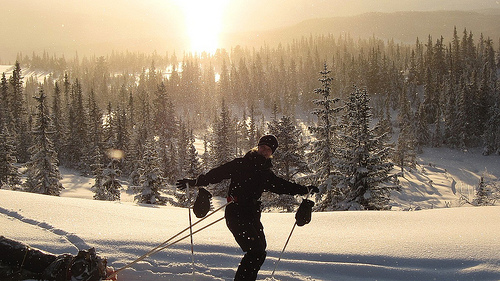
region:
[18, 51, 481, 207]
pine trees in the snow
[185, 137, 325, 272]
a person pulling a sled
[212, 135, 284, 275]
a person wearing a black shirt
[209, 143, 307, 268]
a person with a black cap on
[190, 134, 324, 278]
a person wearing black gloves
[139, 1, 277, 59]
the sun in the sky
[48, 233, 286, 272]
tracks in the snow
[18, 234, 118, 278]
the sled the person is holding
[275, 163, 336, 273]
the stick the person is holding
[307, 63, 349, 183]
a tall snowy tree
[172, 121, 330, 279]
person standing on the snow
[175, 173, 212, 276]
ski pole sticking in the snow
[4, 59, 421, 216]
trees with snow on the branches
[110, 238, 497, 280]
shadows on the ground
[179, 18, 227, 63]
sun in the sky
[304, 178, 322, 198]
hand wrapped around the top of the ski pole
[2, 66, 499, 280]
snow covering the ground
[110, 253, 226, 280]
tracks in the snow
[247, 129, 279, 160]
head is turned to the side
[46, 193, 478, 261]
the snow is perfectly smooth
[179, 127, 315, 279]
a person skiing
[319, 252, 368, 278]
a shadow on the snow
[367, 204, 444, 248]
the snow is white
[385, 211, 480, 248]
the snow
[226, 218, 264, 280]
the women is wearing pants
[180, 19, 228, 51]
the sunlight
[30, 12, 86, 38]
the sky is clear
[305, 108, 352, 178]
snow on the tree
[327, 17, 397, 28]
the mountain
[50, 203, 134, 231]
the white snow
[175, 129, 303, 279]
A man poses on skies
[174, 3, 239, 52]
The sun shines over the mountains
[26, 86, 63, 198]
A snowy tree sits on the mountain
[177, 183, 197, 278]
A sky pole in the hand of the person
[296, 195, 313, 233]
A glove hangs from the pole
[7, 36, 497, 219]
A large group of trees on the mountain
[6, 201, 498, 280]
Snow covers the mountain where the person stands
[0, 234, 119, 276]
The bags of the person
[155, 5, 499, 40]
A mountain in the background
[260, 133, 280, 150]
The skier's hat on their head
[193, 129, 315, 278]
A man skating on snow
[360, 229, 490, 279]
A heap of a snow way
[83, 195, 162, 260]
A heap of a snow way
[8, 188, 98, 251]
A heap of a snow way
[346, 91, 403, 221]
A green tree covered by snow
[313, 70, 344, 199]
A green tree covered by snow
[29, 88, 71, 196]
A green tree covered by snow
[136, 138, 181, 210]
A green tree covered by snow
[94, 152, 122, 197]
A green tree covered by snow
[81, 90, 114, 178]
A green tree covered by snow